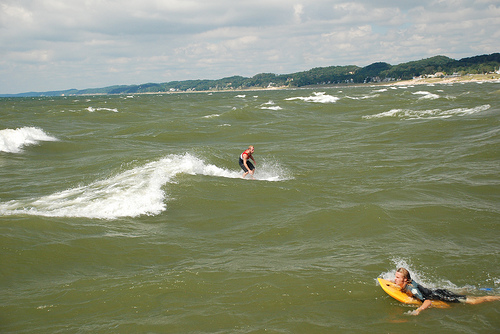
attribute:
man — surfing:
[235, 140, 262, 170]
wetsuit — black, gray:
[409, 271, 459, 303]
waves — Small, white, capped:
[3, 87, 496, 224]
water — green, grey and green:
[1, 93, 491, 333]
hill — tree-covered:
[316, 64, 374, 75]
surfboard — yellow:
[373, 274, 485, 313]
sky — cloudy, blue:
[0, 1, 499, 91]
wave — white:
[25, 149, 295, 226]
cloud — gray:
[10, 43, 55, 68]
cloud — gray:
[285, 15, 373, 46]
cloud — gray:
[411, 18, 476, 36]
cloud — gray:
[194, 20, 258, 45]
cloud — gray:
[104, 45, 175, 72]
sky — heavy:
[2, 1, 496, 82]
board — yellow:
[371, 274, 418, 307]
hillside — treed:
[418, 45, 498, 79]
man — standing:
[231, 140, 263, 180]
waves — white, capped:
[88, 169, 168, 225]